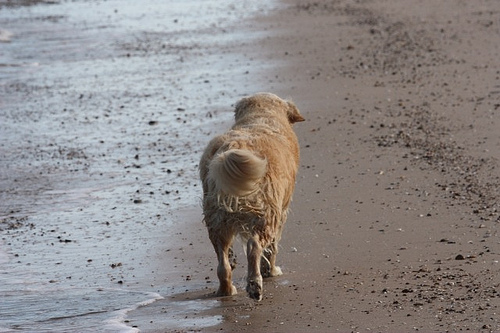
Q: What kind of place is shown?
A: It is a beach.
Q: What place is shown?
A: It is a beach.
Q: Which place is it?
A: It is a beach.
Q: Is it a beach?
A: Yes, it is a beach.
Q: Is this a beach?
A: Yes, it is a beach.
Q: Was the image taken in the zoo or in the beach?
A: It was taken at the beach.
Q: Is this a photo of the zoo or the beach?
A: It is showing the beach.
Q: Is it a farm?
A: No, it is a beach.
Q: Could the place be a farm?
A: No, it is a beach.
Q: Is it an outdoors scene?
A: Yes, it is outdoors.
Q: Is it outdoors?
A: Yes, it is outdoors.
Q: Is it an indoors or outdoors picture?
A: It is outdoors.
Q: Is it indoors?
A: No, it is outdoors.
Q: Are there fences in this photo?
A: No, there are no fences.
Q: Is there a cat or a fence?
A: No, there are no fences or cats.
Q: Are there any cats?
A: No, there are no cats.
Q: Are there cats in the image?
A: No, there are no cats.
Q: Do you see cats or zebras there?
A: No, there are no cats or zebras.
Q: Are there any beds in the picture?
A: No, there are no beds.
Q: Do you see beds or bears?
A: No, there are no beds or bears.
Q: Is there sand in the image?
A: Yes, there is sand.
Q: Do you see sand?
A: Yes, there is sand.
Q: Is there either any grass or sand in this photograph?
A: Yes, there is sand.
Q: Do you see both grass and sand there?
A: No, there is sand but no grass.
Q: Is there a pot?
A: No, there are no pots.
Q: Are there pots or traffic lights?
A: No, there are no pots or traffic lights.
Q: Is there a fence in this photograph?
A: No, there are no fences.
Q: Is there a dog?
A: Yes, there is a dog.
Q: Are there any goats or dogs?
A: Yes, there is a dog.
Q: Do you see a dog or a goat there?
A: Yes, there is a dog.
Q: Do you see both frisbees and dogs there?
A: No, there is a dog but no frisbees.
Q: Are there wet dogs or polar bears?
A: Yes, there is a wet dog.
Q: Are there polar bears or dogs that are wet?
A: Yes, the dog is wet.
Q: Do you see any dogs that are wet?
A: Yes, there is a wet dog.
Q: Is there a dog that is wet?
A: Yes, there is a dog that is wet.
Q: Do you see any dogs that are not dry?
A: Yes, there is a wet dog.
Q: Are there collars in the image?
A: No, there are no collars.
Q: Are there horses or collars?
A: No, there are no collars or horses.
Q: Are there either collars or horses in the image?
A: No, there are no collars or horses.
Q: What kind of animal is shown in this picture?
A: The animal is a dog.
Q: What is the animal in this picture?
A: The animal is a dog.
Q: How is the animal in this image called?
A: The animal is a dog.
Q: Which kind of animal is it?
A: The animal is a dog.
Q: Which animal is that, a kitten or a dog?
A: This is a dog.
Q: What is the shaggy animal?
A: The animal is a dog.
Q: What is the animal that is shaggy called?
A: The animal is a dog.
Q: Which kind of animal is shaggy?
A: The animal is a dog.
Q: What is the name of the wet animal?
A: The animal is a dog.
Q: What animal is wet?
A: The animal is a dog.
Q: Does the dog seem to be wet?
A: Yes, the dog is wet.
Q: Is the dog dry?
A: No, the dog is wet.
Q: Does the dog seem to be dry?
A: No, the dog is wet.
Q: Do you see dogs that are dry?
A: No, there is a dog but it is wet.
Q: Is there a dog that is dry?
A: No, there is a dog but it is wet.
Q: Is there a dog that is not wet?
A: No, there is a dog but it is wet.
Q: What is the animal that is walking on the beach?
A: The animal is a dog.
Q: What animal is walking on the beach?
A: The animal is a dog.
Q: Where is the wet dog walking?
A: The dog is walking on the beach.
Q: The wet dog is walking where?
A: The dog is walking on the beach.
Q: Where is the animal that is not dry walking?
A: The dog is walking on the beach.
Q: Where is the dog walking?
A: The dog is walking on the beach.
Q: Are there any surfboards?
A: No, there are no surfboards.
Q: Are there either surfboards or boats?
A: No, there are no surfboards or boats.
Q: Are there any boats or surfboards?
A: No, there are no surfboards or boats.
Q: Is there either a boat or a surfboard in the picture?
A: No, there are no surfboards or boats.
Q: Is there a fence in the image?
A: No, there are no fences.